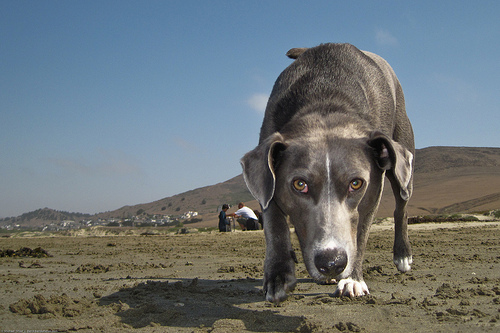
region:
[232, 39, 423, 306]
big dog on a field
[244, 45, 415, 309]
big gray dog with intense look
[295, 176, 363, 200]
two big light brown eyes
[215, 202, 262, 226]
two people in the bag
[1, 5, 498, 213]
light and clear sky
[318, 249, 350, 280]
black nose of big dog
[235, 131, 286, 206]
big right ear of dog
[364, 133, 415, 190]
big left ear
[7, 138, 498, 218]
large mountains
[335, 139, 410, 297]
two left legs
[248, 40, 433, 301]
the dog is grey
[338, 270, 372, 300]
the paw is white in color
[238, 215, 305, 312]
the leg is in the air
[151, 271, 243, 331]
shadow ison the ground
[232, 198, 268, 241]
the man is sitting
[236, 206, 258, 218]
the shirt is white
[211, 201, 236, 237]
the person is a child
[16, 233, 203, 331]
the sand is brown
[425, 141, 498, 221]
the hill is in the background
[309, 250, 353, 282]
the nose is black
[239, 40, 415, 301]
a grey and white dog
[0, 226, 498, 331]
a dirt field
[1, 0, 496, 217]
a blue cloudy sky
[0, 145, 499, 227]
a brown mountain range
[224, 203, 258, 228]
a seated man in distance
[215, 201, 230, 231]
a man standing in distance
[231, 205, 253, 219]
a long sleeve white shirt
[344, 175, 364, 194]
a dog's left eye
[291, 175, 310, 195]
a dog's right eye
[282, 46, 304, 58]
a dog's grey tail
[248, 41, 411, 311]
A dog looking straight ahead.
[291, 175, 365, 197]
The dog's brown eyes.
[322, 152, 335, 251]
A white stripe on the dog's nose.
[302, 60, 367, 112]
The grey fur on the dog.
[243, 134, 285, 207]
The dog's right ear.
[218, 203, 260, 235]
Two people in the distance.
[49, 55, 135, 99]
Part of the blue sky.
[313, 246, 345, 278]
The dog's black nose.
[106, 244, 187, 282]
Part of the brown dirt.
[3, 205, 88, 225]
A mountain in the distance.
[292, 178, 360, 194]
Dog two eyes.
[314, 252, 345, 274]
Black dog nose.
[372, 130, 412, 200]
Dog's right ear.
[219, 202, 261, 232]
Two people sitting on the beach.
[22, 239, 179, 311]
Dark gray sand on beach.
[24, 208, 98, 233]
Mountain hillside in background.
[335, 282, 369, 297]
Dog's white paw.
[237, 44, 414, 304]
Large gray dog.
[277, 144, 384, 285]
Dog's face close up.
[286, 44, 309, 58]
Dog's gray tail.